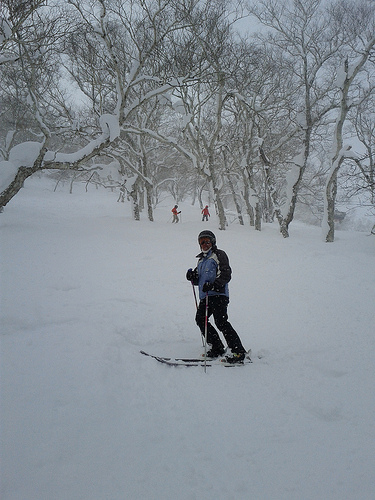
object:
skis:
[140, 346, 240, 371]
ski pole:
[204, 290, 209, 362]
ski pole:
[191, 281, 200, 309]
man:
[185, 230, 247, 362]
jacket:
[194, 247, 232, 300]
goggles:
[197, 237, 212, 244]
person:
[169, 203, 181, 223]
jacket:
[171, 206, 178, 216]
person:
[199, 204, 211, 222]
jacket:
[202, 208, 210, 216]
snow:
[1, 177, 374, 498]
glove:
[186, 266, 196, 285]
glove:
[210, 279, 226, 294]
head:
[197, 230, 216, 257]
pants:
[194, 295, 245, 355]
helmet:
[197, 229, 215, 242]